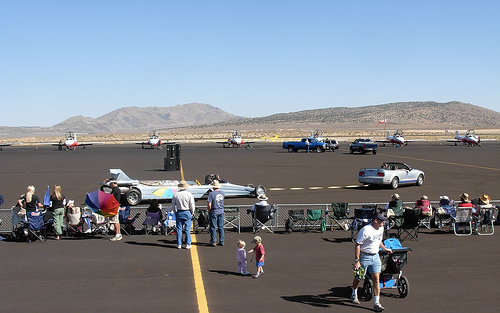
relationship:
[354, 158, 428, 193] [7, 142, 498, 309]
car on tarmac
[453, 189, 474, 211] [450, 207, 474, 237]
person sitting in chair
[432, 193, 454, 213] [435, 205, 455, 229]
person sitting in chair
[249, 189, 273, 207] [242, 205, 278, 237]
person sitting in lawn chair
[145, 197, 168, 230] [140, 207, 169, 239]
person sitting in lawn chair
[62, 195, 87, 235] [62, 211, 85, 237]
person sitting in lawn chair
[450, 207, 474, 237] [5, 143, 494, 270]
chair on tarmac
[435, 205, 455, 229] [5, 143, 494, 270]
chair on tarmac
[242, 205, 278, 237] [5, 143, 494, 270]
lawn chair on tarmac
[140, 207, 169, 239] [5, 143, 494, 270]
lawn chair on tarmac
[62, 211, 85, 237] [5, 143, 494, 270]
lawn chair on tarmac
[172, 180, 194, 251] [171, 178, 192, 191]
man wearing hat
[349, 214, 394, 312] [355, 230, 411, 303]
man pulling stroller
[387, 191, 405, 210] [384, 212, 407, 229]
person sitting in a chair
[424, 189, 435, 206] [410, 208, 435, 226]
person sitting in a chair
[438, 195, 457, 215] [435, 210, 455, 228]
person sitting in a chair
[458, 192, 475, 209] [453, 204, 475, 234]
person sitting in a chair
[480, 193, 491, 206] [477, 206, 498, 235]
person sitting in a chair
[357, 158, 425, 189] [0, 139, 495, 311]
car on road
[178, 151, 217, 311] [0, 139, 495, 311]
yellow line on road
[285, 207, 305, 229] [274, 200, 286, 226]
lawn chair in front of gate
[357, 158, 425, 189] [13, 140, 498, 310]
car on airport track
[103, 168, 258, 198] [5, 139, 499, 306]
car on track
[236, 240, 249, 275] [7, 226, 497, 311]
child playing on track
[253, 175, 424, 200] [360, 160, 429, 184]
line behind mustang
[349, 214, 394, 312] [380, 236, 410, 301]
man pulling baby stroller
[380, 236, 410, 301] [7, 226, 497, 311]
baby stroller on track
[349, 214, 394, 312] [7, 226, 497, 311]
man on track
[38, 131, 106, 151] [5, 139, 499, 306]
airplane at track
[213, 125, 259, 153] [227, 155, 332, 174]
airplane at a track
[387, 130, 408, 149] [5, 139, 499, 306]
airplane at a track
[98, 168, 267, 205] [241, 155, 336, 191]
car at a track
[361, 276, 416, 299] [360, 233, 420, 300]
wheels on a stroller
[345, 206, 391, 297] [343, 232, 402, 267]
man wearing shirt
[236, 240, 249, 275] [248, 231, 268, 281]
child standing with kid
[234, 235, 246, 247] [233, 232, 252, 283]
hair of child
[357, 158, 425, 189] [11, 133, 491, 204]
car on track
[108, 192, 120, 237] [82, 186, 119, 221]
man holding umbrella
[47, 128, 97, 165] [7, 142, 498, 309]
plane on tarmac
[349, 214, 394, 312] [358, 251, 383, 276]
man in blue shorts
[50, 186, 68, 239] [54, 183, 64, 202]
woman with hair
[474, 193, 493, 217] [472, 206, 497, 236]
person sitting on chair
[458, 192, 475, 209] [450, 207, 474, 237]
person sitting on chair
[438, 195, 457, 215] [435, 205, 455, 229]
person sitting on chair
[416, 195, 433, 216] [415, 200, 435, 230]
person sitting on chair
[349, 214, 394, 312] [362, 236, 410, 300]
man pulling stroller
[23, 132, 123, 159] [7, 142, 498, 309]
airplane on tarmac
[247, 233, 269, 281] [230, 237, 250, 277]
child playing with child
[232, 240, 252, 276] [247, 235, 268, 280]
child playing with child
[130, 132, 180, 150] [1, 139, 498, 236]
airplane at track